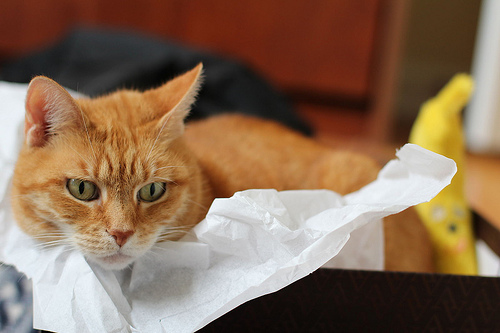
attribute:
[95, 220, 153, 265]
nose — pink, part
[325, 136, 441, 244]
paper — white, crumpled, cumpled, part, edge, crinkled, rip, crumbled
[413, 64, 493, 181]
object — yellow, mark, corner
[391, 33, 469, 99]
door — brown, white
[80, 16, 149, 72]
cloth — black, edge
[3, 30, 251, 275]
cat — orange, lying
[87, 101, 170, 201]
stripe — orange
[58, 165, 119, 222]
eye — green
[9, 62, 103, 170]
ear — edge, pink, brown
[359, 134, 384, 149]
floor — brown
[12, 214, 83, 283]
whisker — white